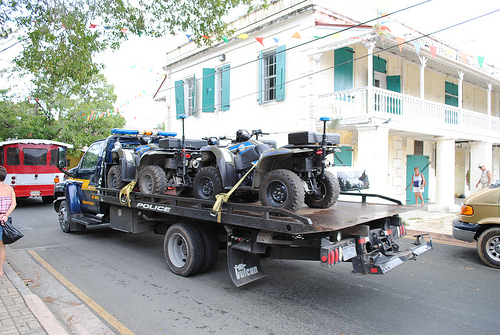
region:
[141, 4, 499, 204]
a white building on left side of road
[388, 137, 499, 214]
people in front a white buillding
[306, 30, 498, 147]
a balcony in front a building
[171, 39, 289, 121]
doors of windows are blue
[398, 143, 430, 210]
a blue door of a white building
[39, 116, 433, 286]
a truck carrying motorcycles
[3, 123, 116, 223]
a red bus in front a truck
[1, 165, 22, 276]
woman holding a black bag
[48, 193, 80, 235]
front wheel of truck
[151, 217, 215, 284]
back wheel of truck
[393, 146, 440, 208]
a woman at the sidewalk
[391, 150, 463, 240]
a woman at the sidewalk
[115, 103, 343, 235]
dirt bikes on the truck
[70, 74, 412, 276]
dirt bikes on the truck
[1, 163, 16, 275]
the woman on the sidewalk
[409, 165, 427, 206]
the woman standing in front of the building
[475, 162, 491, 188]
the man in front of the building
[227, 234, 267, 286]
the mud flap on the truck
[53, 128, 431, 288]
the truck and trailer on the road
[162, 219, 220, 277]
the wheels on the truck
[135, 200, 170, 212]
the word POLICE on the trailer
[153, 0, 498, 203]
the building near the road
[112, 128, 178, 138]
the lights on the truck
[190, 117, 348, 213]
the vehicle on the trailer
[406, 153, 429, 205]
bright blue open door on lower story of building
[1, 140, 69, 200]
red and white bus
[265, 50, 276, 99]
open window on second story of building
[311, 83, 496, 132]
white balcony on second floor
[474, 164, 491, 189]
man in white walking into building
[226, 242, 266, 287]
black mud flap with white lettering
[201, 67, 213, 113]
teal blue window shutter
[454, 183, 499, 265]
front of gold minivan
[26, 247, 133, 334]
yellow line on the road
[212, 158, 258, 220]
yellow tie down rope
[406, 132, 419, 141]
part of a balcony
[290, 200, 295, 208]
part of a wheel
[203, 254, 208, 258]
edge of a wheel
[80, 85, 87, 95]
part of a tree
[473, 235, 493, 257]
part of a wheel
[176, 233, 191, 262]
part of a wheel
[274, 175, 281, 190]
edge of a wheel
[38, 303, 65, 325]
edge of a road